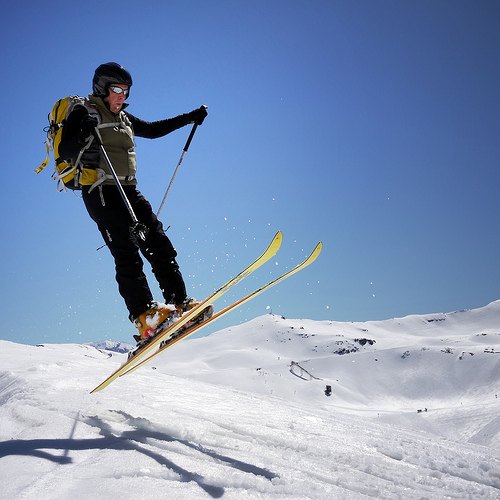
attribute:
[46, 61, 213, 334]
man — skiing, airborne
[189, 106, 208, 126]
hand — black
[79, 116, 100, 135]
hand — black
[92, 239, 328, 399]
skis — yellow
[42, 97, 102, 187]
backpack — yellow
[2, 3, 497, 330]
sky — blue, clear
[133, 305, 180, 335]
boot — orange, yellow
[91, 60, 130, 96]
helmet — black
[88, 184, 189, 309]
pants — black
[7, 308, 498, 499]
snow — white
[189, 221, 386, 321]
snow — flying